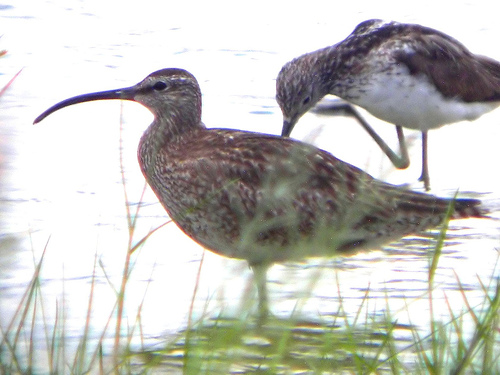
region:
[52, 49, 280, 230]
brown bird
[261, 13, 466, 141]
brown bird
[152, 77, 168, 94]
eye of frontmost bird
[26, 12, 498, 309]
two birds in water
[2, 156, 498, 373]
grass in front of birds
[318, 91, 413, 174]
crooked leg of back most bird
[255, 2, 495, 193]
bird with white underbelly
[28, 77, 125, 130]
long beak of front most bird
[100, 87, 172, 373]
tall blade of grass with spindles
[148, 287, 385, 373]
shadow on water cast by bird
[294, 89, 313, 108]
eye on back most bird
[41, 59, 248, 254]
brown bird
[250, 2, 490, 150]
brown bird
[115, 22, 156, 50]
white clouds in blue sky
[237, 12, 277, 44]
white clouds in blue sky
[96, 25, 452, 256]
two birds in water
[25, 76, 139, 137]
long pointy beak on bird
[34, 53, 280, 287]
bird with long beak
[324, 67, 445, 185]
bird lifting leg to scratch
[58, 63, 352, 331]
sandpiper standing in water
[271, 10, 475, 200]
sandpiper standing in water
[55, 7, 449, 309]
pair of sandpipers in water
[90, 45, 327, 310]
bird with spotted feathers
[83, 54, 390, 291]
sandpipers looking for food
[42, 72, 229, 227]
brown bird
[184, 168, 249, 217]
feathers on the bird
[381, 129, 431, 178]
the birds legs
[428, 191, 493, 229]
the birds tail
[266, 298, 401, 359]
the grass is long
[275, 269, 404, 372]
the long green grass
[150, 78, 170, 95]
the birds eye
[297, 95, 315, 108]
the eye of the bird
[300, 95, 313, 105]
left eye of the bird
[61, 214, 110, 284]
the water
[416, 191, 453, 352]
A grass in some water.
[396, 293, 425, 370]
A grass in some water.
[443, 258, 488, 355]
A grass in some water.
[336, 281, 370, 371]
A grass in some water.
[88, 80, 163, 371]
A grass in some water.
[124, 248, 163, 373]
A grass in some water.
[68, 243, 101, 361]
A grass in some water.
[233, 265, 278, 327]
legs of the bird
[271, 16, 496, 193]
bird scratching with his foot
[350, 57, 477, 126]
white belly of the bird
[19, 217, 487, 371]
green grass along the water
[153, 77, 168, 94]
black eye of the bird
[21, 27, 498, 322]
brown and white birds in the water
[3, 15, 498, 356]
water the birds are standing in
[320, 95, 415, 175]
bent leg of the bird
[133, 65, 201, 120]
head of the bird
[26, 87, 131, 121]
black beak on bird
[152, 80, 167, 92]
small eye on bird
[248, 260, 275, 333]
thin leg on bird